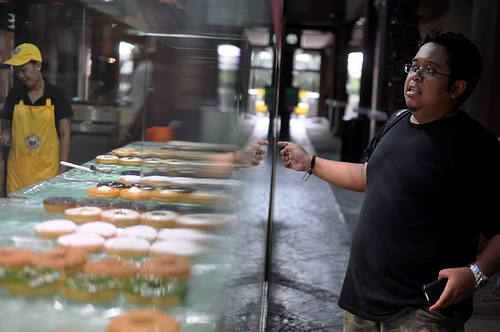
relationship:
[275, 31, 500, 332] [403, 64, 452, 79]
man wearing glasses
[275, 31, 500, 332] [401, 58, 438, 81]
man wearing glasses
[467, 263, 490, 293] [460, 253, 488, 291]
watch on wrist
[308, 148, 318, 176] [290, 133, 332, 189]
band on wrist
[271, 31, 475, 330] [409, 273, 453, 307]
man holding phone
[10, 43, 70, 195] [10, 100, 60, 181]
person wearing apron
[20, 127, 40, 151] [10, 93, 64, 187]
logo on apron